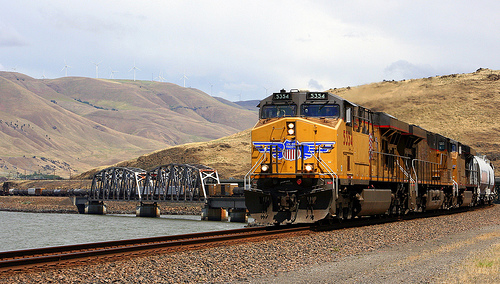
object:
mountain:
[323, 67, 500, 177]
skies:
[0, 0, 500, 103]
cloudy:
[0, 0, 500, 102]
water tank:
[466, 155, 497, 208]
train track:
[0, 187, 249, 202]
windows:
[298, 102, 343, 120]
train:
[241, 87, 500, 228]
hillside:
[75, 128, 251, 180]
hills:
[0, 71, 261, 180]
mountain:
[69, 128, 254, 179]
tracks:
[0, 223, 311, 272]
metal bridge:
[85, 162, 221, 201]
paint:
[250, 140, 335, 160]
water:
[0, 211, 247, 253]